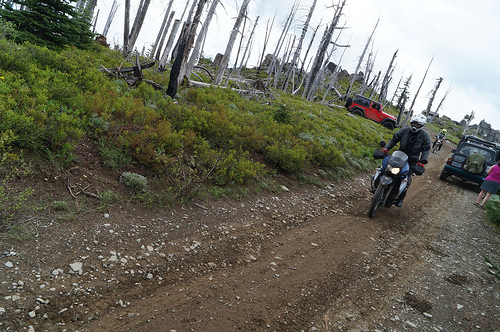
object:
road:
[2, 123, 495, 325]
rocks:
[0, 195, 421, 330]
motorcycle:
[368, 151, 417, 219]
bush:
[0, 42, 72, 148]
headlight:
[391, 168, 400, 175]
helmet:
[409, 113, 427, 133]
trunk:
[156, 19, 182, 71]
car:
[440, 135, 500, 188]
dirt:
[69, 242, 341, 330]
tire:
[369, 181, 390, 218]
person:
[369, 113, 431, 208]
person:
[473, 162, 500, 209]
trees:
[89, 0, 451, 127]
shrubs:
[0, 40, 400, 183]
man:
[431, 129, 448, 151]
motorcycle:
[431, 136, 446, 154]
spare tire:
[459, 154, 487, 180]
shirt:
[484, 164, 500, 181]